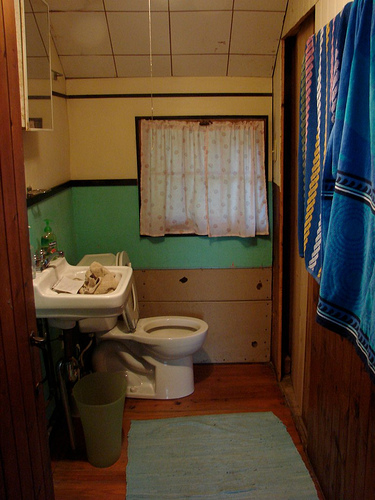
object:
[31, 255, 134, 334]
sink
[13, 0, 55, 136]
cabinet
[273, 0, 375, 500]
wall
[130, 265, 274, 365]
cabinet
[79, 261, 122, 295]
towel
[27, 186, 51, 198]
dish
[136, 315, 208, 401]
white bowl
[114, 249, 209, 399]
toilet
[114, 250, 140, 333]
toilet lid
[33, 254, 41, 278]
faucet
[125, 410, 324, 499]
boards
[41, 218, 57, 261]
soap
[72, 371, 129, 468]
garbage can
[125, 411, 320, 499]
floor rug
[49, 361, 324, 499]
floor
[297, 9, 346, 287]
towel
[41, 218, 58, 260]
bottle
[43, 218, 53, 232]
lid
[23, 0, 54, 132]
mirror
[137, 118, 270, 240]
curtain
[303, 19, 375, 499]
door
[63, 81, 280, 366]
wall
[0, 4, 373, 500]
bathroom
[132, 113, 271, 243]
window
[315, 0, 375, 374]
shower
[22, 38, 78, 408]
wall